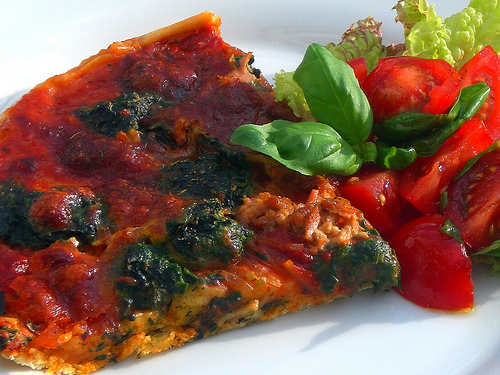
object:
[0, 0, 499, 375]
plate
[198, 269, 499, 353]
shadow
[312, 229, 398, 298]
food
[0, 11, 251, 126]
crust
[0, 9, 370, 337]
cheese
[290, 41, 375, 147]
leaves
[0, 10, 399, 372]
spices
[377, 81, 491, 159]
leaves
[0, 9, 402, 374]
pizza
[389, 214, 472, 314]
tomato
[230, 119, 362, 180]
green leaves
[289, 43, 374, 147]
veggies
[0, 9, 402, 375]
slice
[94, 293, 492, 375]
surface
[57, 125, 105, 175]
red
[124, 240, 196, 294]
green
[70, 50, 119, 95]
golden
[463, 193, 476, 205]
seeds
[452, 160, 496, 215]
within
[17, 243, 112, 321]
melted